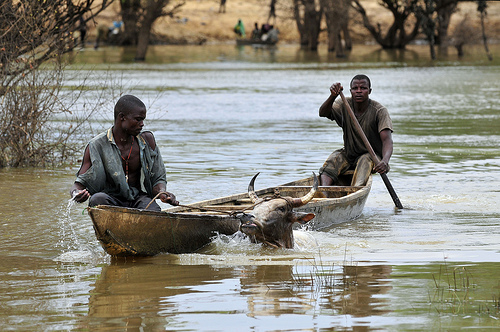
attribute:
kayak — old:
[86, 163, 374, 264]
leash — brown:
[142, 188, 293, 217]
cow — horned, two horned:
[236, 170, 321, 251]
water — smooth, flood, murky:
[1, 64, 499, 332]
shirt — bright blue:
[112, 20, 123, 31]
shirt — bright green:
[235, 23, 245, 34]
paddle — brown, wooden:
[336, 83, 402, 212]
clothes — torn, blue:
[74, 129, 166, 213]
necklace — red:
[108, 131, 138, 183]